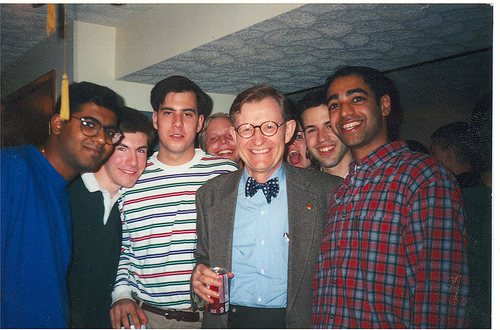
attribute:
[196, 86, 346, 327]
old man — smiling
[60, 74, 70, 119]
tassel — gold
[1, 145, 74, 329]
blue shirt — plain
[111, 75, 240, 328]
man — not smiling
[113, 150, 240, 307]
striped shirt — long sleeved, multi-colored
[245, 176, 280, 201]
bow tie — black, white, plaid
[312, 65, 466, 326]
man — smiling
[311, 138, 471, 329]
plaid shirt — red, blue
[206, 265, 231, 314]
soda can — open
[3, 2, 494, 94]
ceiling — white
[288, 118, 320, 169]
person — excited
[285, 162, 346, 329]
blazer — gray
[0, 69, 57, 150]
door — brown